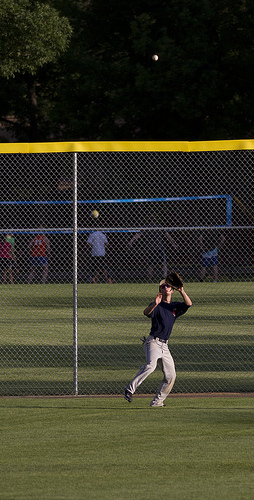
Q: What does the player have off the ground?
A: Right foot.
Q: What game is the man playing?
A: Baseball.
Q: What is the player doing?
A: Catching a baseball.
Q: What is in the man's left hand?
A: A glove.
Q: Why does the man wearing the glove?
A: To catch the baseball.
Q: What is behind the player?
A: Fence.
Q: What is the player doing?
A: Waiting for the ball.